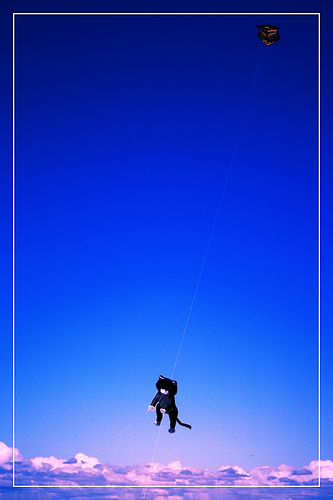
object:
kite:
[256, 22, 282, 48]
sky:
[0, 0, 332, 499]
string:
[170, 45, 266, 379]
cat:
[147, 374, 192, 433]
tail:
[175, 413, 192, 431]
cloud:
[0, 440, 332, 499]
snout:
[159, 385, 170, 397]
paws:
[147, 402, 155, 413]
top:
[1, 4, 332, 141]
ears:
[157, 373, 167, 381]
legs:
[168, 414, 178, 434]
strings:
[140, 410, 167, 499]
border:
[12, 11, 321, 492]